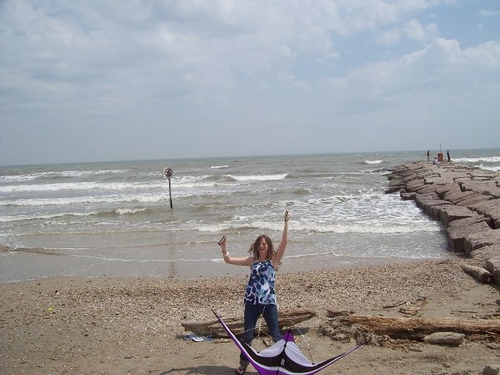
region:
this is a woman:
[194, 201, 339, 345]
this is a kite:
[194, 296, 369, 372]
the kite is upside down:
[186, 293, 381, 373]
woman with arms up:
[199, 210, 323, 272]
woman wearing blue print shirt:
[231, 261, 288, 329]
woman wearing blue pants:
[228, 290, 288, 365]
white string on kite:
[214, 265, 331, 359]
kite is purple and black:
[208, 305, 377, 372]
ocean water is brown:
[48, 168, 408, 253]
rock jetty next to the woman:
[382, 142, 499, 312]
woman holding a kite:
[170, 197, 335, 374]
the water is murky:
[40, 142, 355, 232]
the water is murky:
[222, 156, 309, 218]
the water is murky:
[190, 158, 304, 242]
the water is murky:
[187, 144, 272, 212]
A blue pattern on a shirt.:
[243, 256, 278, 306]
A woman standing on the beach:
[216, 208, 293, 370]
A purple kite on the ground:
[211, 305, 365, 372]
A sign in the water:
[162, 165, 175, 208]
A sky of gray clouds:
[2, 4, 494, 142]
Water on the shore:
[3, 167, 145, 284]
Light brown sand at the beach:
[7, 280, 175, 371]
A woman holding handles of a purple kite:
[210, 208, 366, 371]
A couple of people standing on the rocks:
[426, 148, 452, 163]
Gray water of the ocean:
[1, 157, 428, 228]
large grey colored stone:
[446, 225, 486, 251]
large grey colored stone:
[448, 212, 488, 229]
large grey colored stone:
[441, 203, 469, 223]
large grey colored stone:
[484, 200, 499, 222]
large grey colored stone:
[458, 193, 488, 205]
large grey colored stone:
[445, 187, 468, 203]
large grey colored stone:
[406, 178, 422, 189]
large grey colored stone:
[403, 173, 415, 183]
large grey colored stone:
[422, 175, 455, 183]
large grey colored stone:
[473, 174, 488, 181]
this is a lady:
[189, 218, 339, 366]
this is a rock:
[450, 212, 488, 254]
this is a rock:
[441, 197, 480, 232]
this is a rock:
[410, 190, 458, 230]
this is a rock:
[447, 180, 472, 227]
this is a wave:
[217, 179, 285, 211]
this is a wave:
[243, 190, 318, 252]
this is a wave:
[326, 205, 371, 242]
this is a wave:
[263, 202, 315, 242]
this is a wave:
[26, 184, 94, 226]